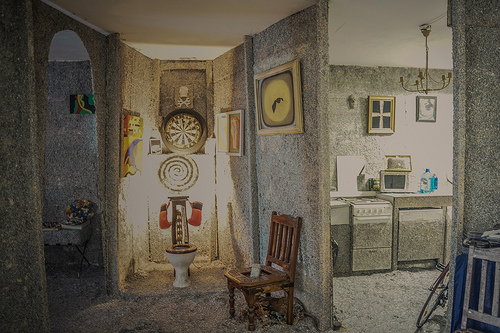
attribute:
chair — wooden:
[223, 207, 303, 330]